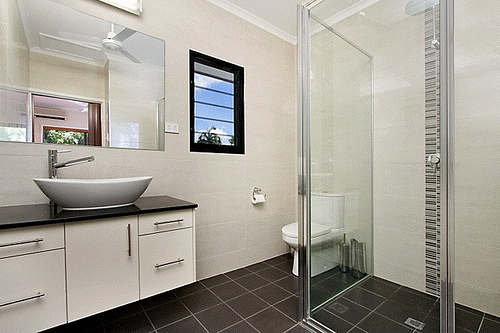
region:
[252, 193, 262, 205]
a roll of tissue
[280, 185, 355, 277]
a white toilet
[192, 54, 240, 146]
a bathroom window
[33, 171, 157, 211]
a large white sink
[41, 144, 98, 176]
a gray sink faucet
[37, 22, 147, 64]
a white ceiling fan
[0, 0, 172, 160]
part of a wall mirror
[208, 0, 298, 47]
part of a white ceiling trim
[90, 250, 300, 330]
part of brown floor tile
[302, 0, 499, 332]
a glass shower door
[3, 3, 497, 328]
a modern bathroom is gray tiled floors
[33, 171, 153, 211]
an above counter sink is in the bathroom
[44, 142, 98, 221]
the faucet for the sink is chrome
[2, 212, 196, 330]
white cabinets are in the bathroom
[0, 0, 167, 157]
a mirror is above the sink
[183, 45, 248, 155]
a window is in the bathroom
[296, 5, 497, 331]
the shower is glass enclosed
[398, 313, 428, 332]
a drain is in the bottom of the shower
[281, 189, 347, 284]
the toilet is white next to the shower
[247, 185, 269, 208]
a toilet paper holder is on the wall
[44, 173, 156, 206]
A sink displays a white bowl.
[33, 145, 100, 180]
A silver faucet is attached to a vanity.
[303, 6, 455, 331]
A shower has clear showerdoors.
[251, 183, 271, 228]
Toilet paper is hanging from the wall.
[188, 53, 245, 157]
A window has black trim.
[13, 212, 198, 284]
A vanity has silver handles.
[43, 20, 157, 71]
A fan is reflecting from a mirror.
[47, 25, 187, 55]
A fan is hanging from a ceiling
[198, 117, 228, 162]
Trees are outside a bathroom.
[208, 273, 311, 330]
Grey tiles are installed on the floor.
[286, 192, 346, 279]
white toilet in the bathroom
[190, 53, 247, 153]
small window with black pane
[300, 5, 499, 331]
clear glass shower in bathroom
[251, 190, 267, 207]
toilet paper roll on the wall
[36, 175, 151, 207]
sink bowl on the counter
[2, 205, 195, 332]
large vanity with black top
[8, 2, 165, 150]
mirror above the sink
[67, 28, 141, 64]
reflection of ceiling fan in mirror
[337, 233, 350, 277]
silver toilet brush holder by toilet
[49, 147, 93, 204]
silver faucet for sink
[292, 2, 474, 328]
see-through glass shower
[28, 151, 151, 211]
white raised sink basin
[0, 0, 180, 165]
mirror above counter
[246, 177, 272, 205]
toilet paper on a roll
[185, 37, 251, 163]
window with black frame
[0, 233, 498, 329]
black tile with white grout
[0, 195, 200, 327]
white cabinets with chrome hardware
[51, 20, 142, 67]
ceiling fan visible in reflection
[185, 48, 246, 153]
blue sky with white clouds outside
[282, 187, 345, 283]
white toilet seat in the corner